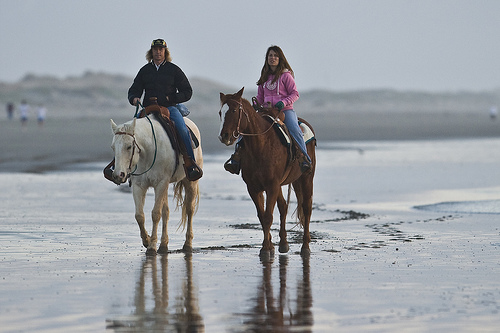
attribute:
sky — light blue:
[0, 0, 499, 95]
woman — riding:
[220, 39, 317, 182]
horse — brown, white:
[212, 85, 319, 260]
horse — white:
[93, 97, 214, 264]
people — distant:
[36, 100, 48, 129]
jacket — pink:
[254, 69, 306, 111]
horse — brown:
[216, 87, 341, 252]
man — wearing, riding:
[137, 30, 184, 90]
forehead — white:
[219, 97, 230, 134]